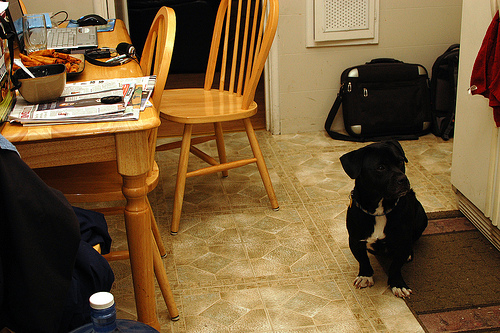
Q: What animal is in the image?
A: A dog.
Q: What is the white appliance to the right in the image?
A: A refrigerator.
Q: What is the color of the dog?
A: Black.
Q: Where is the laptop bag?
A: Leaning on the wall.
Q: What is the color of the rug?
A: Brown.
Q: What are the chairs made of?
A: Wood.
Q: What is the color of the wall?
A: Beige.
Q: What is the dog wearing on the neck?
A: A collar.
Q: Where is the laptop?
A: On the table.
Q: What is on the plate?
A: Food.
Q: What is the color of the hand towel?
A: Red.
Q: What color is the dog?
A: Black and white.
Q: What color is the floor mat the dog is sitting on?
A: Brown.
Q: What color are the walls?
A: Light beige.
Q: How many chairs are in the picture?
A: Two.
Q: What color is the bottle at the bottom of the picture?
A: Blue.